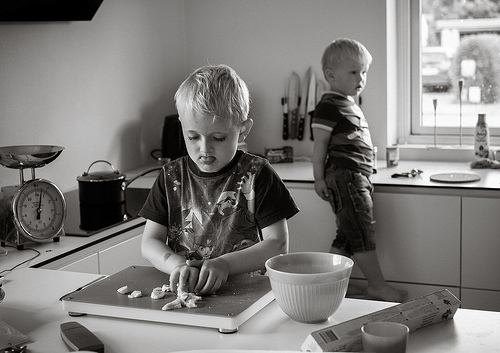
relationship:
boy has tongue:
[136, 57, 301, 299] [197, 153, 218, 166]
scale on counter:
[0, 142, 71, 253] [0, 149, 499, 352]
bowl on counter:
[264, 248, 357, 325] [0, 149, 499, 352]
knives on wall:
[278, 65, 328, 143] [182, 0, 393, 166]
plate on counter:
[427, 169, 484, 187] [0, 149, 499, 352]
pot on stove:
[76, 158, 169, 235] [40, 183, 158, 239]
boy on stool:
[303, 35, 412, 305] [337, 289, 389, 302]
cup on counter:
[355, 318, 412, 353] [0, 149, 499, 352]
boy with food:
[136, 57, 301, 299] [114, 281, 204, 314]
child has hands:
[136, 57, 301, 299] [165, 254, 232, 298]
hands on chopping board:
[165, 254, 232, 298] [58, 264, 288, 336]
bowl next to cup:
[264, 248, 357, 325] [355, 318, 412, 353]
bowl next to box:
[264, 248, 357, 325] [298, 283, 465, 352]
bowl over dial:
[0, 142, 66, 172] [11, 176, 70, 245]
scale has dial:
[0, 142, 71, 253] [11, 176, 70, 245]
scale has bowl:
[0, 142, 71, 253] [0, 142, 66, 172]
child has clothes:
[303, 35, 412, 305] [308, 86, 382, 256]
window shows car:
[384, 0, 499, 152] [417, 42, 454, 93]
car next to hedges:
[417, 42, 454, 93] [448, 30, 499, 108]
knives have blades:
[278, 65, 328, 143] [280, 66, 331, 115]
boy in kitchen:
[136, 63, 301, 295] [0, 0, 499, 353]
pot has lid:
[76, 158, 169, 235] [76, 158, 130, 186]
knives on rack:
[278, 65, 328, 143] [277, 94, 364, 108]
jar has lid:
[383, 143, 400, 169] [383, 144, 400, 152]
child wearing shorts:
[303, 35, 412, 305] [317, 157, 381, 256]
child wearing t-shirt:
[136, 57, 301, 299] [138, 148, 300, 271]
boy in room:
[136, 63, 301, 295] [0, 0, 499, 353]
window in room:
[384, 0, 499, 152] [0, 0, 499, 353]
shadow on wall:
[109, 75, 186, 178] [0, 0, 188, 204]